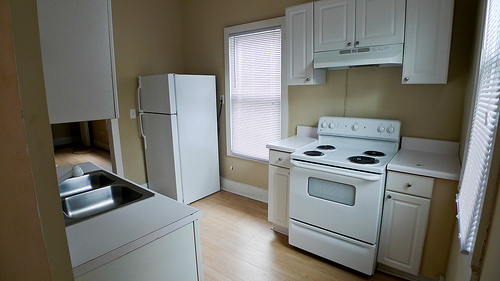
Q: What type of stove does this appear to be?
A: Electric.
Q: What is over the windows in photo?
A: Blinds.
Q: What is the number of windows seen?
A: 2.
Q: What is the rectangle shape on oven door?
A: Window.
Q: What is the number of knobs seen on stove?
A: 5.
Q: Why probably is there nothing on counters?
A: New house.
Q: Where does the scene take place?
A: In a kitchen.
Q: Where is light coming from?
A: Windows.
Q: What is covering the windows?
A: Blinds.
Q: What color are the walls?
A: Tan.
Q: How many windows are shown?
A: Two.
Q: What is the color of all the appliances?
A: White.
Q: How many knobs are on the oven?
A: Five.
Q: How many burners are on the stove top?
A: Four.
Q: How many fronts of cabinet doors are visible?
A: Six.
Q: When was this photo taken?
A: Day time.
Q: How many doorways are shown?
A: One.